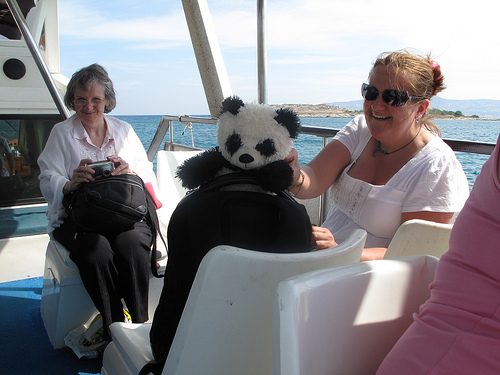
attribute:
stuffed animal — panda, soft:
[174, 95, 301, 197]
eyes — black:
[223, 132, 277, 158]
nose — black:
[238, 153, 255, 166]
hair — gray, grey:
[64, 63, 117, 114]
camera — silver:
[83, 159, 116, 181]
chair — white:
[98, 228, 373, 374]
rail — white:
[145, 1, 496, 166]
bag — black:
[62, 170, 163, 235]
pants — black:
[54, 209, 157, 341]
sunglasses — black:
[360, 82, 431, 108]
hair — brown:
[369, 50, 445, 137]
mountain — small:
[260, 105, 499, 125]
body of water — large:
[108, 115, 498, 208]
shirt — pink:
[372, 135, 498, 374]